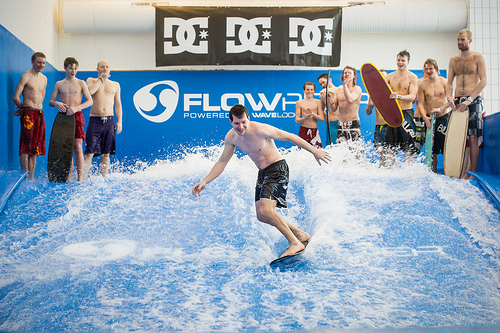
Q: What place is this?
A: It is a swimming pool.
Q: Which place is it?
A: It is a swimming pool.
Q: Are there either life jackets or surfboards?
A: Yes, there is a surfboard.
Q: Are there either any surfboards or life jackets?
A: Yes, there is a surfboard.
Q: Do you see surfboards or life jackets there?
A: Yes, there is a surfboard.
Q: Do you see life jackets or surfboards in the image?
A: Yes, there is a surfboard.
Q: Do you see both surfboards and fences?
A: No, there is a surfboard but no fences.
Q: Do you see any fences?
A: No, there are no fences.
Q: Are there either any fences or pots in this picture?
A: No, there are no fences or pots.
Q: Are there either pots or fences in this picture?
A: No, there are no fences or pots.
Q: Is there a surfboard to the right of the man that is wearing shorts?
A: Yes, there is a surfboard to the right of the man.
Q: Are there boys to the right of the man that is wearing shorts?
A: No, there is a surfboard to the right of the man.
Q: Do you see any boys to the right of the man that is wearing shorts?
A: No, there is a surfboard to the right of the man.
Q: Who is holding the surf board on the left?
A: The man is holding the surfboard.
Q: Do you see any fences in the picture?
A: No, there are no fences.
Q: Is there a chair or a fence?
A: No, there are no fences or chairs.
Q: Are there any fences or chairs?
A: No, there are no fences or chairs.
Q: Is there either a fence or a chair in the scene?
A: No, there are no fences or chairs.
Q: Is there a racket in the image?
A: No, there are no rackets.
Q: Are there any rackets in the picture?
A: No, there are no rackets.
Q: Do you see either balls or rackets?
A: No, there are no rackets or balls.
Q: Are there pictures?
A: No, there are no pictures.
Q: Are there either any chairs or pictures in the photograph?
A: No, there are no pictures or chairs.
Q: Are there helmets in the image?
A: No, there are no helmets.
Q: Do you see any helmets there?
A: No, there are no helmets.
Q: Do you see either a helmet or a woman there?
A: No, there are no helmets or women.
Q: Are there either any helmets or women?
A: No, there are no helmets or women.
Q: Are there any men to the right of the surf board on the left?
A: Yes, there is a man to the right of the surfboard.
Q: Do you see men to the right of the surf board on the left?
A: Yes, there is a man to the right of the surfboard.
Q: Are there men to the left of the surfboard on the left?
A: No, the man is to the right of the surfboard.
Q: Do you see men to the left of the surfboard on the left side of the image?
A: No, the man is to the right of the surfboard.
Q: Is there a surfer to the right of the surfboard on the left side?
A: No, there is a man to the right of the surf board.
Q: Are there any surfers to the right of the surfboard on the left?
A: No, there is a man to the right of the surf board.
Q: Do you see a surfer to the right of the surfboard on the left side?
A: No, there is a man to the right of the surf board.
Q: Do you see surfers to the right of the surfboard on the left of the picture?
A: No, there is a man to the right of the surf board.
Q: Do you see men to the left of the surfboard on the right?
A: Yes, there is a man to the left of the surfboard.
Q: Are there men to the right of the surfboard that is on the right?
A: No, the man is to the left of the surfboard.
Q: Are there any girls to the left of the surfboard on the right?
A: No, there is a man to the left of the surf board.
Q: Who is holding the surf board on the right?
A: The man is holding the surfboard.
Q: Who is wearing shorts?
A: The man is wearing shorts.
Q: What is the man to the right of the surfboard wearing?
A: The man is wearing shorts.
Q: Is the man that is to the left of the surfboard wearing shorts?
A: Yes, the man is wearing shorts.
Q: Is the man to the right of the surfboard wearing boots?
A: No, the man is wearing shorts.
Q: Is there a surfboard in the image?
A: Yes, there is a surfboard.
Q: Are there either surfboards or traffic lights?
A: Yes, there is a surfboard.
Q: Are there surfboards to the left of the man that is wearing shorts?
A: Yes, there is a surfboard to the left of the man.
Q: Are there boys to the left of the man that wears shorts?
A: No, there is a surfboard to the left of the man.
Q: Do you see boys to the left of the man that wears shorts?
A: No, there is a surfboard to the left of the man.